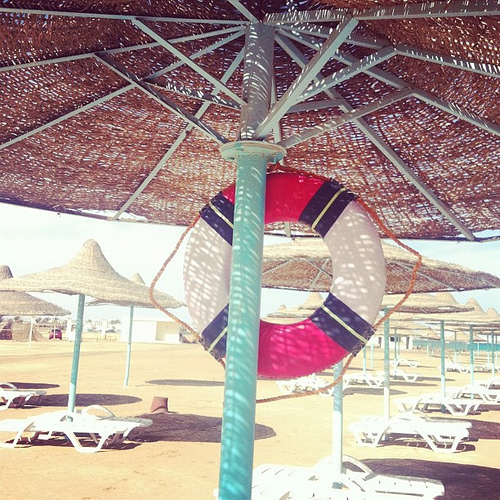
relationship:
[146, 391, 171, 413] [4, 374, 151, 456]
barrel next to lounge chair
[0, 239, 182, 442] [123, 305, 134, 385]
umbrella on pole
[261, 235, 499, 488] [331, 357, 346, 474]
umbrella on pole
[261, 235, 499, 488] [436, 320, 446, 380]
umbrella on blue pole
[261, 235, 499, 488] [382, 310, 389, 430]
umbrella on pole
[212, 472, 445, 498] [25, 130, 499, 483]
beach chair on beach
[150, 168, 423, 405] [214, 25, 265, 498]
life saver on pole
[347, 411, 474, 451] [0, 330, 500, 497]
beach chair on ground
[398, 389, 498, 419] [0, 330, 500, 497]
chair at ground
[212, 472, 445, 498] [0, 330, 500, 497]
beach chair at ground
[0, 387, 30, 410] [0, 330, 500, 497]
beach chair at ground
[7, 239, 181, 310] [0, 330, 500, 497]
umbrella on ground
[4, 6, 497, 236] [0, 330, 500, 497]
umbrella on ground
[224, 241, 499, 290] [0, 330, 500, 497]
umbrella on ground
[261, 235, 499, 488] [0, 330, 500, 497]
umbrella on ground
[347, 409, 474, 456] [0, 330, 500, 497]
beach chair on ground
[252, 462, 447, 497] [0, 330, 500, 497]
beach chair on ground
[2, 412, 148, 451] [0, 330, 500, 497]
beach chair on ground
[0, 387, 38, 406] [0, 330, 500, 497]
beach chair on ground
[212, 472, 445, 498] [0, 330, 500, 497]
beach chair on ground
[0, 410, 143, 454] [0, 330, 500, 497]
beach chair on ground